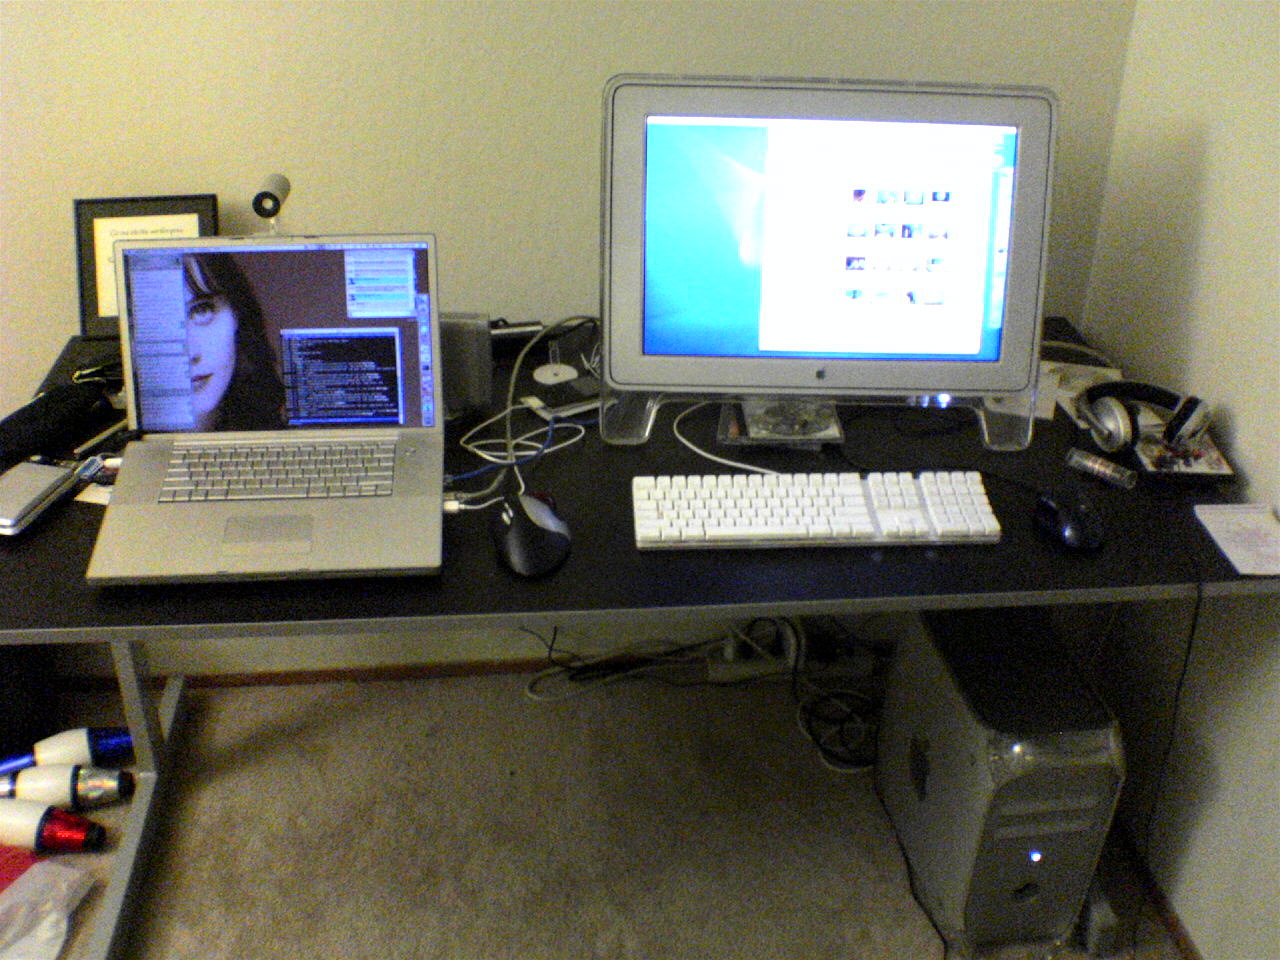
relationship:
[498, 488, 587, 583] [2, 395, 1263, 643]
mouse on table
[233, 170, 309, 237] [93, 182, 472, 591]
webcam on computer